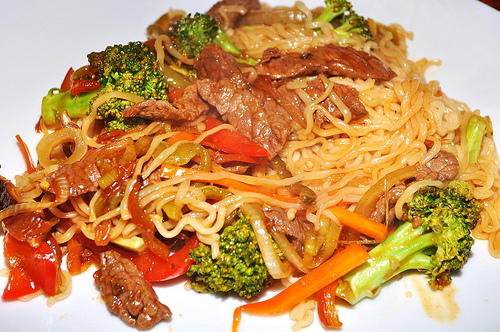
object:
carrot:
[239, 241, 369, 316]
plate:
[2, 2, 498, 331]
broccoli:
[339, 186, 480, 304]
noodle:
[146, 185, 224, 239]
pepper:
[3, 229, 63, 301]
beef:
[194, 44, 400, 148]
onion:
[152, 141, 214, 174]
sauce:
[419, 284, 461, 324]